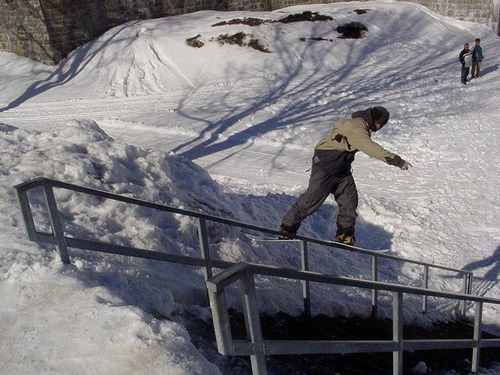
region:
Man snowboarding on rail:
[257, 95, 409, 249]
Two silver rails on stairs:
[0, 180, 498, 374]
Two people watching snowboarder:
[453, 35, 488, 85]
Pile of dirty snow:
[6, 120, 240, 258]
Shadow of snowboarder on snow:
[440, 224, 499, 286]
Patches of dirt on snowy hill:
[186, 6, 366, 51]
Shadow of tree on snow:
[166, 50, 340, 166]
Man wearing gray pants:
[265, 97, 398, 232]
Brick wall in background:
[5, 10, 77, 62]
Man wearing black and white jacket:
[457, 41, 474, 86]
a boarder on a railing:
[261, 102, 410, 241]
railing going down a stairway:
[14, 166, 480, 314]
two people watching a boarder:
[450, 31, 493, 85]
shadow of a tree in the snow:
[170, 10, 465, 165]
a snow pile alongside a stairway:
[22, 119, 360, 286]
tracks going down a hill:
[108, 21, 197, 94]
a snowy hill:
[34, 6, 491, 59]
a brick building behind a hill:
[2, 1, 290, 73]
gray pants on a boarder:
[270, 150, 376, 228]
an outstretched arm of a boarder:
[338, 120, 422, 172]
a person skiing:
[222, 41, 469, 301]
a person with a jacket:
[229, 55, 419, 227]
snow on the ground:
[87, 14, 264, 177]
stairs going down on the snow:
[12, 115, 465, 373]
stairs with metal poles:
[34, 67, 474, 364]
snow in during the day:
[129, 17, 414, 209]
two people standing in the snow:
[419, 10, 497, 117]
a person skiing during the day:
[189, 48, 469, 282]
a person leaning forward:
[264, 50, 491, 277]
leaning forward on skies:
[278, 56, 443, 276]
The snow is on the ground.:
[116, 46, 321, 110]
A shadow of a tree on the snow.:
[169, 1, 392, 139]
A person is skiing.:
[301, 101, 413, 231]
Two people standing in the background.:
[436, 36, 488, 90]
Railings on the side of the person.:
[38, 187, 460, 303]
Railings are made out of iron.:
[205, 268, 441, 373]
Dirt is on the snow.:
[193, 23, 375, 55]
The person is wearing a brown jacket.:
[318, 113, 402, 171]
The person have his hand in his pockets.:
[458, 40, 478, 79]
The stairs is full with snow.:
[33, 250, 207, 365]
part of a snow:
[427, 120, 476, 182]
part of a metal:
[207, 310, 232, 352]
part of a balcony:
[241, 211, 294, 271]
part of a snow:
[103, 316, 150, 344]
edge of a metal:
[206, 273, 243, 304]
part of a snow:
[86, 267, 138, 318]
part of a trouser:
[306, 175, 319, 195]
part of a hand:
[395, 157, 417, 170]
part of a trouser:
[316, 176, 346, 219]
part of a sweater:
[314, 145, 334, 163]